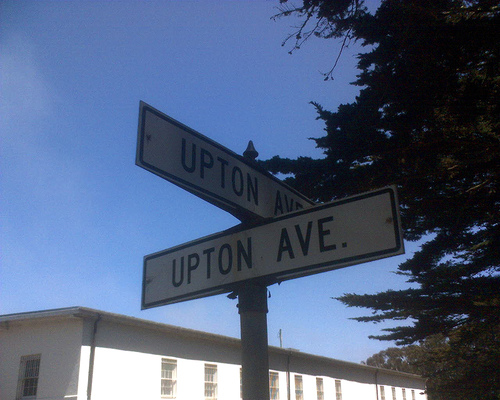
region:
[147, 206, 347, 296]
street sign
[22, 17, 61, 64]
white clouds in blue sky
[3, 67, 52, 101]
white clouds in blue sky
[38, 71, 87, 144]
white clouds in blue sky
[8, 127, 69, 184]
white clouds in blue sky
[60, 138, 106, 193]
white clouds in blue sky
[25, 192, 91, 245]
white clouds in blue sky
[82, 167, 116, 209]
white clouds in blue sky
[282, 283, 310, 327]
white clouds in blue sky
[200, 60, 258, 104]
white clouds in blue sky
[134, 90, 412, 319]
white sign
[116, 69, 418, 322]
sign has black lines on edge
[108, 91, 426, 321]
its a street sign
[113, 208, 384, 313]
it says upton ave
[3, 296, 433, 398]
the building is white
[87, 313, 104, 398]
the down spout is brown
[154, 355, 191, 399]
there is glass in the windows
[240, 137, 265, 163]
the top of the post is pointy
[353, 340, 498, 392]
the leaves in the tree are green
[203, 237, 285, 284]
the sign has rust stains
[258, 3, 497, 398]
tree to the right of the sign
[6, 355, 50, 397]
only visible window on this side of the building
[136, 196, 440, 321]
sign on the bottom of the two signs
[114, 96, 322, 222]
sign on the top of two signs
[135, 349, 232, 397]
two windows to the left of the sign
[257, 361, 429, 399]
eight windows to the right of the pole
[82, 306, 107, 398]
gutter drain going down the side of the building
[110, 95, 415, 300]
two signs that have the words "Upton Ave." written on them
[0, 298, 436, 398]
white building shown in the background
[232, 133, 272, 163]
spike on the top of the pole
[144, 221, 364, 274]
blue and white street sign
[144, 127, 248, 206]
blue and white street sign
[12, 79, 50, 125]
white clouds in blue sky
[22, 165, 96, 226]
white clouds in blue sky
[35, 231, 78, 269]
white clouds in blue sky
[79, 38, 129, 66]
white clouds in blue sky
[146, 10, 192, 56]
white clouds in blue sky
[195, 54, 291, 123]
white clouds in blue sky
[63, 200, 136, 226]
white clouds in blue sky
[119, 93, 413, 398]
white signs on a pole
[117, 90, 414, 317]
signs borders are black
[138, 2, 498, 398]
green trees on side signs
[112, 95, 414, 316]
the letters "UPTON AVE." in both signs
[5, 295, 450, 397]
a white house behind two signs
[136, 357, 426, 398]
windows below the roof of building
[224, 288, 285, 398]
pole of signs is gray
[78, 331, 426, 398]
sun is shining on side the building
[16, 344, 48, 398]
a window in front a building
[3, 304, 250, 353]
gray gutters on roof